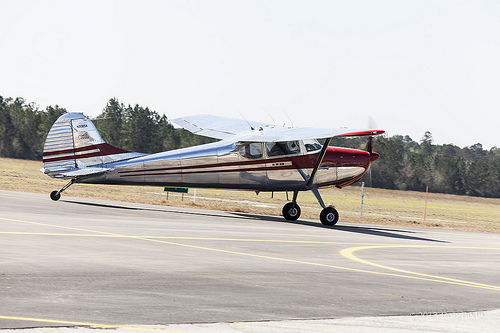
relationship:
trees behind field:
[0, 95, 499, 198] [0, 157, 498, 236]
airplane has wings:
[43, 112, 386, 226] [169, 112, 385, 141]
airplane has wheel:
[43, 112, 386, 226] [282, 202, 302, 219]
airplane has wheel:
[43, 112, 386, 226] [320, 206, 340, 226]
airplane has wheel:
[43, 112, 386, 226] [49, 189, 61, 200]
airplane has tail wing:
[43, 112, 386, 226] [62, 165, 113, 182]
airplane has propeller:
[43, 112, 386, 226] [367, 110, 377, 207]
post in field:
[423, 186, 431, 223] [0, 157, 498, 236]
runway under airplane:
[1, 189, 499, 330] [43, 112, 386, 226]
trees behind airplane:
[0, 95, 499, 198] [43, 112, 386, 226]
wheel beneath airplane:
[282, 202, 302, 219] [43, 112, 386, 226]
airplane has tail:
[43, 112, 386, 226] [43, 112, 147, 177]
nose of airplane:
[329, 145, 380, 184] [43, 112, 386, 226]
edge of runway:
[1, 305, 499, 331] [1, 189, 499, 330]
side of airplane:
[43, 114, 381, 226] [43, 112, 386, 226]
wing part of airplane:
[243, 125, 386, 156] [43, 112, 386, 226]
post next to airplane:
[358, 180, 367, 220] [43, 112, 386, 226]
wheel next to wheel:
[282, 202, 302, 219] [320, 206, 340, 226]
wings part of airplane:
[169, 112, 385, 141] [43, 112, 386, 226]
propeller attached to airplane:
[367, 110, 377, 207] [43, 112, 386, 226]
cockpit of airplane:
[236, 138, 326, 189] [43, 112, 386, 226]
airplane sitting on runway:
[43, 112, 386, 226] [1, 189, 499, 330]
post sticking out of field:
[423, 186, 431, 223] [0, 157, 498, 236]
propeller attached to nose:
[367, 110, 377, 207] [329, 145, 380, 184]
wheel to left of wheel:
[282, 202, 302, 219] [320, 206, 340, 226]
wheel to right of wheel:
[320, 206, 340, 226] [282, 202, 302, 219]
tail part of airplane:
[43, 112, 147, 177] [43, 112, 386, 226]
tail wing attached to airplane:
[62, 165, 113, 182] [43, 112, 386, 226]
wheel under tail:
[49, 189, 61, 200] [43, 112, 147, 177]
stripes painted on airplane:
[118, 155, 292, 178] [43, 112, 386, 226]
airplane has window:
[43, 112, 386, 226] [239, 141, 264, 159]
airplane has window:
[43, 112, 386, 226] [266, 141, 301, 156]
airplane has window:
[43, 112, 386, 226] [303, 140, 322, 151]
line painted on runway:
[3, 214, 472, 287] [1, 189, 499, 330]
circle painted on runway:
[339, 242, 499, 293] [1, 189, 499, 330]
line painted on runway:
[0, 229, 430, 249] [1, 189, 499, 330]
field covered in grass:
[0, 157, 498, 236] [1, 156, 499, 232]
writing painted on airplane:
[270, 159, 287, 168] [43, 112, 386, 226]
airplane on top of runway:
[43, 112, 386, 226] [1, 189, 499, 330]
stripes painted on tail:
[41, 143, 101, 163] [43, 112, 147, 177]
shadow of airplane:
[60, 198, 451, 244] [43, 112, 386, 226]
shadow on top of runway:
[60, 198, 451, 244] [1, 189, 499, 330]